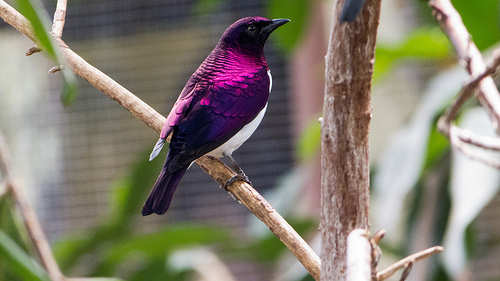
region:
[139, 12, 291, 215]
bird standing on branch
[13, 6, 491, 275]
thin branches of tree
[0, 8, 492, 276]
green leaves in background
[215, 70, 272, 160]
white chest of bird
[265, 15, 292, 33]
beak on bird's face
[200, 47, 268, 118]
pink and purple feathers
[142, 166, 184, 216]
tail feathers of bird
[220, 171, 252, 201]
foot wrapped around branch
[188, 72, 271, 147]
wing on side of bird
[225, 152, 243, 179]
thin leg of bird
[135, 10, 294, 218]
a bird perched on a branch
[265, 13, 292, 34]
the beak of a bird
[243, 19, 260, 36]
the eye of a bird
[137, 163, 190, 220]
the tail of a bird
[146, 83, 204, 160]
the wind of a bird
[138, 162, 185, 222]
the feathers of a the tail of a bird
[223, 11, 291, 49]
the head of a bird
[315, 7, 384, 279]
a stalk of a weed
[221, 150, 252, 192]
the leg of a bird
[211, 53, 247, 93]
the feathers of a bird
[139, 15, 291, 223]
A small, purple bird on a branch.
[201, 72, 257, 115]
Feathers on a small, purple bird.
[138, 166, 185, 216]
Tail feathers of a purple bird.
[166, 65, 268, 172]
A wing on a purple bird.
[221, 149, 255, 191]
A bird's foot wrapped around a branch.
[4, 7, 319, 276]
A thin branch with a bird on it.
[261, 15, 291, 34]
The black beak of a small bird.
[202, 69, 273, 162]
White breast on a purple bird.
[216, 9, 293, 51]
Head of a small bird.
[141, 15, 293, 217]
A bird with shiny, purple feathers.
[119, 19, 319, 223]
a pink and purple bird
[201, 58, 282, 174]
a white belly on bird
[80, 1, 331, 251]
a bird on a branch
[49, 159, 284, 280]
green leaves in the background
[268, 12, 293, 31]
small black beak on bird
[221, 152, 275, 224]
small leg on bird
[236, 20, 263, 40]
an eye of the bird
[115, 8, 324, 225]
a bird on a limb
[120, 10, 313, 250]
a purple bird on limb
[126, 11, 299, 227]
violet-backed or amethyst starling. yow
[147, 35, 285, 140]
feathers really are irridescent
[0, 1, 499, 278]
picture, if it's in the wild, is in sub-saharan africa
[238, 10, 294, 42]
finally, a truly black beak [bill]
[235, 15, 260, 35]
large black pupilled eye, with a bright yellow iris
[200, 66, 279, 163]
a beautiful, polished white breast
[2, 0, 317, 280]
shadowed window blinds on a white or pink building in back